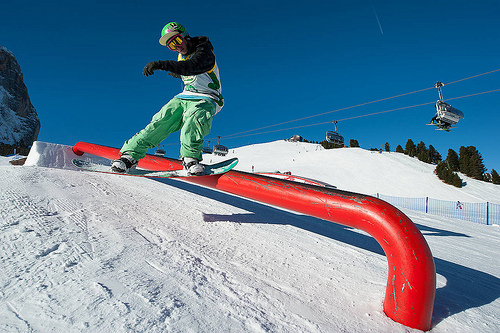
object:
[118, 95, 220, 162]
green pants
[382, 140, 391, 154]
tree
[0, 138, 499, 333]
snowy hill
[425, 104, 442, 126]
people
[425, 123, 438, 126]
skis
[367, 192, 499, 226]
net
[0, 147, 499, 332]
ski slope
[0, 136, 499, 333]
snow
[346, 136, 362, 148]
tree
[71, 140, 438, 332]
rail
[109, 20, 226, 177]
snowboarder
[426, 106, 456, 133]
people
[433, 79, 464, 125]
lift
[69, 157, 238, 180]
snowboard